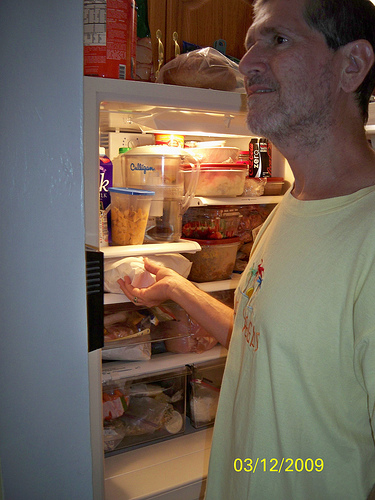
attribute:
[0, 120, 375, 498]
refrigerator — full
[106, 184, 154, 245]
container — is plastic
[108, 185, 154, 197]
lid — is blue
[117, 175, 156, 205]
top — blue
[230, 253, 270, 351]
design — red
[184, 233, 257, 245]
lid — blue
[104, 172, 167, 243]
lid — is blue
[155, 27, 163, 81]
handle — is golden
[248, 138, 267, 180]
soda — black, red, white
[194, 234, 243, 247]
top — red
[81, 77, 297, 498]
refrigerator — is open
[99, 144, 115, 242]
steps — is blue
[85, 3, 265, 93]
cabinet — is wooden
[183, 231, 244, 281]
container — is plastic